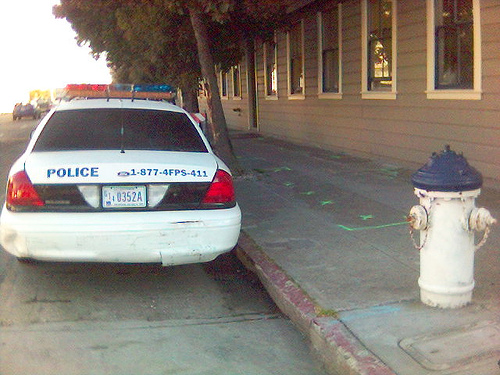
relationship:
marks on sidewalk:
[277, 173, 298, 190] [197, 113, 497, 373]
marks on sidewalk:
[299, 184, 316, 199] [197, 113, 497, 373]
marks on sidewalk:
[315, 195, 338, 212] [197, 113, 497, 373]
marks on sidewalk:
[356, 208, 376, 224] [197, 113, 497, 373]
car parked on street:
[3, 69, 265, 285] [2, 109, 332, 373]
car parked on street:
[0, 83, 243, 268] [0, 261, 281, 373]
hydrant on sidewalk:
[405, 142, 497, 312] [197, 113, 497, 373]